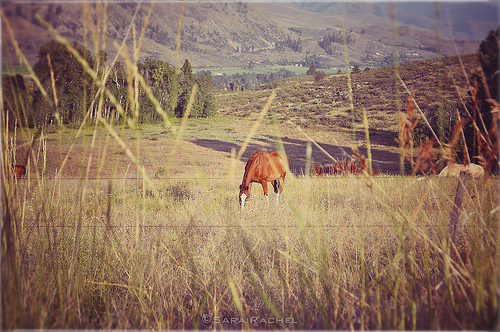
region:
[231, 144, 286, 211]
a horse standing in the middle of the field eating grass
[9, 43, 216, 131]
a line of tall trees off on the side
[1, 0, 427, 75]
an almost bare hill off to the side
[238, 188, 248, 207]
the white stripe on the horse's face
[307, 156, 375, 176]
possibly some more horses in the field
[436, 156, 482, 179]
the rock off to the side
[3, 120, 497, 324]
the tall weeds next to the camera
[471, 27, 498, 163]
another tall leafy tree in the field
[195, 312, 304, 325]
the name and copyright on the bottom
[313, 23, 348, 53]
a few more trees on the hill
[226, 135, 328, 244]
a horse in the field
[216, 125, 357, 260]
a lone horse in a field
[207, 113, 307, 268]
a horse standing in grass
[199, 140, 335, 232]
a brown and white horse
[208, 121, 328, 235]
a horse by itself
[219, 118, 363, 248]
a horse eating grass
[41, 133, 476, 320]
a large field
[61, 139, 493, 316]
a vast field with grass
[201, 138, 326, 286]
a horse standing alone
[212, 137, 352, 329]
a horse with a white face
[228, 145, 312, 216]
a horse inside of a pen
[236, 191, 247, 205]
white face of the horse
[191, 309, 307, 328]
name and copyright of the photographer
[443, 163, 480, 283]
dence post for the pen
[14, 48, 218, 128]
green trees growing in the distance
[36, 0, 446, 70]
rolling hills in the distance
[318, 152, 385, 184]
brown plants growing in the field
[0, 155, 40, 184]
the back end of a brown horse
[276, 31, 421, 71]
several white buildings in the distance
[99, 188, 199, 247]
overgrown green grass of the field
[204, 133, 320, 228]
brown horse with white marking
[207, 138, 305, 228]
brown horse grazing on a hill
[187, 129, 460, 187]
water in the distance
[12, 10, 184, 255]
heads of grain in the foreground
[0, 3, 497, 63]
hillside in the distance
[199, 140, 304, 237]
brown horse eating grass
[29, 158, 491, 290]
barb wire fence with wooden posts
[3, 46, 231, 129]
a row of green trees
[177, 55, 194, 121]
an evergreen tree in the distance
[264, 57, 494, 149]
foliage on the hillside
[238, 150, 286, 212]
Brown and white horse grazing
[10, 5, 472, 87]
Mountains in back ground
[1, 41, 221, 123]
Row of tall green trees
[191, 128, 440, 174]
Shadows of trees on the grass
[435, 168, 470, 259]
Brown fence post with wires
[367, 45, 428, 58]
White buildings in back ground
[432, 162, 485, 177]
White horse grazing on grass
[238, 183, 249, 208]
Brown horse with white face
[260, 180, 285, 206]
Brown and white legs of horse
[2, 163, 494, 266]
Barbed wire fence